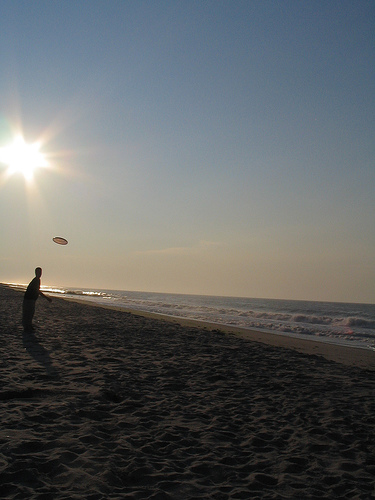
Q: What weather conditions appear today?
A: It is clear.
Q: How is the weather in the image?
A: It is clear.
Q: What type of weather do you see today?
A: It is clear.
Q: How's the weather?
A: It is clear.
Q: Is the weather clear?
A: Yes, it is clear.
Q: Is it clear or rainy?
A: It is clear.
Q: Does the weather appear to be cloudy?
A: No, it is clear.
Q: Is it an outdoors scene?
A: Yes, it is outdoors.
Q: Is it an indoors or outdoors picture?
A: It is outdoors.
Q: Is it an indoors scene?
A: No, it is outdoors.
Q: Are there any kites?
A: No, there are no kites.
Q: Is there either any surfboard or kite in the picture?
A: No, there are no kites or surfboards.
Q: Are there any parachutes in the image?
A: No, there are no parachutes.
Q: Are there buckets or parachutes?
A: No, there are no parachutes or buckets.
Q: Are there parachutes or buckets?
A: No, there are no parachutes or buckets.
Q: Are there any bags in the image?
A: No, there are no bags.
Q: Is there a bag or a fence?
A: No, there are no bags or fences.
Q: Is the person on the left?
A: Yes, the person is on the left of the image.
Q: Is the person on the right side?
A: No, the person is on the left of the image.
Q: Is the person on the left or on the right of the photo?
A: The person is on the left of the image.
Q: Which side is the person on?
A: The person is on the left of the image.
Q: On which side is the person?
A: The person is on the left of the image.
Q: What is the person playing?
A: The person is playing frisbee.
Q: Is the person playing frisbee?
A: Yes, the person is playing frisbee.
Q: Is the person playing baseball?
A: No, the person is playing frisbee.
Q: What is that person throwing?
A: The person is throwing the frisbee.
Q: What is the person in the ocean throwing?
A: The person is throwing the frisbee.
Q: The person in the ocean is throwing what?
A: The person is throwing the frisbee.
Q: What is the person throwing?
A: The person is throwing the frisbee.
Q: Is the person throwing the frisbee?
A: Yes, the person is throwing the frisbee.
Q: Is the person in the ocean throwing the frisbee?
A: Yes, the person is throwing the frisbee.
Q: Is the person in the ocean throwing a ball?
A: No, the person is throwing the frisbee.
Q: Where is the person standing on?
A: The person is standing on the sand.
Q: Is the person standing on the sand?
A: Yes, the person is standing on the sand.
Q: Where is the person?
A: The person is in the ocean.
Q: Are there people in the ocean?
A: Yes, there is a person in the ocean.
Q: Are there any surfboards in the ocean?
A: No, there is a person in the ocean.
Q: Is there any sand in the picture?
A: Yes, there is sand.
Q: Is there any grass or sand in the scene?
A: Yes, there is sand.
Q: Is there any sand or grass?
A: Yes, there is sand.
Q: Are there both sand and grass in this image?
A: No, there is sand but no grass.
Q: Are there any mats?
A: No, there are no mats.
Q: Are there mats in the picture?
A: No, there are no mats.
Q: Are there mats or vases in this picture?
A: No, there are no mats or vases.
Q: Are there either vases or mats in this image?
A: No, there are no mats or vases.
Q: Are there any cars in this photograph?
A: No, there are no cars.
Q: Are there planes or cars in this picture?
A: No, there are no cars or planes.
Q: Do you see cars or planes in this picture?
A: No, there are no cars or planes.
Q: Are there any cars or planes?
A: No, there are no cars or planes.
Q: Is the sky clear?
A: Yes, the sky is clear.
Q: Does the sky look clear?
A: Yes, the sky is clear.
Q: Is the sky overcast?
A: No, the sky is clear.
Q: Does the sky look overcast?
A: No, the sky is clear.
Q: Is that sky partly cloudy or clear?
A: The sky is clear.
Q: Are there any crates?
A: No, there are no crates.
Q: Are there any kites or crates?
A: No, there are no crates or kites.